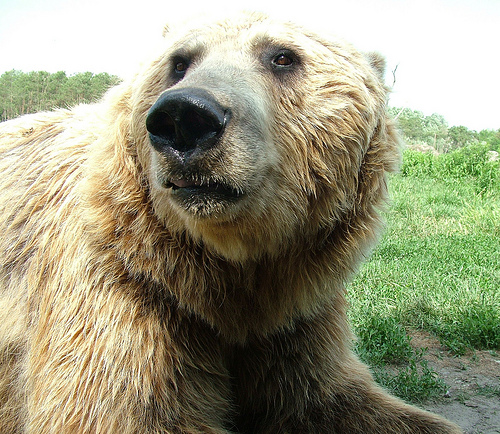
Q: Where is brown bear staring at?
A: Camera.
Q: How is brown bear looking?
A: Curious.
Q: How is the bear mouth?
A: Slightly open.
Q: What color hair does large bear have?
A: Brown.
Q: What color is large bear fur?
A: Brown.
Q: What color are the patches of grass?
A: Green.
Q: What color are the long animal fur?
A: Brown.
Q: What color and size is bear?
A: Brown and large.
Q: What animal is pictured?
A: Bear.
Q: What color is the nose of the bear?
A: Black.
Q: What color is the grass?
A: Green.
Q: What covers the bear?
A: Fur.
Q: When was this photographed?
A: Day light.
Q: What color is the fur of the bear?
A: Brown.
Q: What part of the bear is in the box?
A: Neck.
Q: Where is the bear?
A: A field.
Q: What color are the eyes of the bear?
A: Black.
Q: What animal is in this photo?
A: A bear.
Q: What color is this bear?
A: Brown.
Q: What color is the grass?
A: Green.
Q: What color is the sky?
A: White.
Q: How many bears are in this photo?
A: One.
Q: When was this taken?
A: During the day.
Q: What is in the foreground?
A: A bear.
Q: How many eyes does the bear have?
A: Two.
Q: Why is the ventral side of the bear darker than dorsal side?
A: There is no light on it.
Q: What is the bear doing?
A: Looking to it's right.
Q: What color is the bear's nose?
A: Black.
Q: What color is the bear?
A: Golden brown.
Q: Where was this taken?
A: In a field.